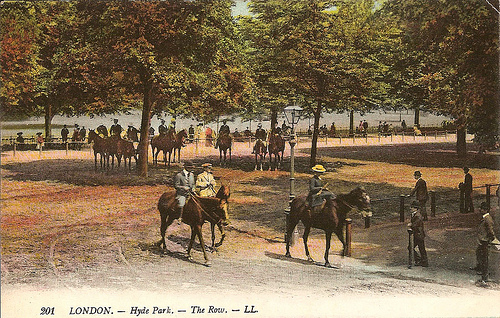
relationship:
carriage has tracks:
[230, 174, 337, 249] [86, 235, 138, 273]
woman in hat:
[162, 149, 234, 223] [301, 164, 342, 202]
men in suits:
[143, 154, 223, 192] [168, 166, 220, 186]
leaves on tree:
[69, 22, 119, 64] [143, 23, 204, 72]